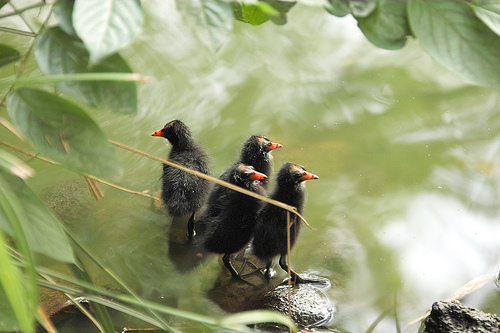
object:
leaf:
[357, 0, 412, 51]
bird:
[250, 163, 329, 288]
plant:
[0, 0, 500, 333]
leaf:
[326, 0, 373, 17]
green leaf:
[0, 83, 125, 175]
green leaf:
[406, 0, 500, 88]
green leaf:
[0, 173, 80, 271]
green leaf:
[175, 1, 229, 55]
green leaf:
[70, 0, 144, 69]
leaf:
[29, 23, 137, 114]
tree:
[0, 0, 498, 330]